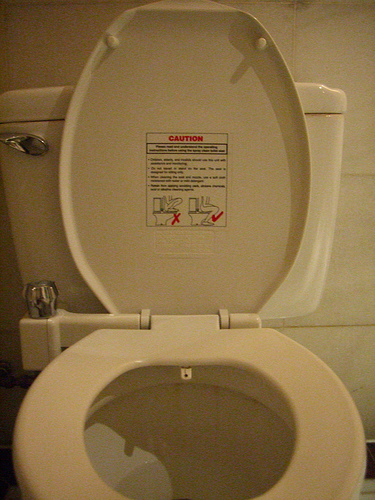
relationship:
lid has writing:
[58, 0, 309, 314] [168, 135, 202, 141]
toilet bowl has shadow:
[5, 329, 369, 498] [78, 359, 302, 498]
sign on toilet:
[146, 132, 228, 228] [2, 3, 368, 498]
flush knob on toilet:
[0, 123, 53, 159] [2, 3, 368, 498]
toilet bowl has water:
[5, 329, 369, 498] [105, 443, 261, 499]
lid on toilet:
[54, 11, 315, 320] [5, 14, 347, 488]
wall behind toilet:
[9, 16, 352, 374] [2, 3, 368, 498]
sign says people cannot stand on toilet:
[141, 128, 233, 232] [150, 194, 177, 225]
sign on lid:
[146, 132, 228, 228] [58, 0, 309, 314]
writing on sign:
[166, 130, 204, 141] [146, 132, 228, 228]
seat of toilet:
[11, 319, 362, 490] [5, 14, 347, 488]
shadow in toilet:
[85, 383, 293, 498] [2, 3, 368, 498]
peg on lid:
[100, 31, 121, 46] [58, 0, 309, 314]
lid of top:
[7, 79, 347, 126] [9, 83, 345, 328]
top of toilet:
[9, 83, 345, 328] [5, 14, 347, 488]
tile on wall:
[293, 8, 357, 172] [12, 6, 362, 330]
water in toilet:
[130, 468, 241, 491] [2, 3, 368, 498]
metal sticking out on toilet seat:
[177, 368, 189, 380] [9, 316, 359, 487]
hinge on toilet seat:
[137, 305, 152, 328] [9, 316, 359, 487]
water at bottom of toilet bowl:
[123, 453, 241, 490] [88, 365, 278, 497]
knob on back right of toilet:
[19, 278, 68, 314] [2, 3, 368, 498]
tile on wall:
[294, 8, 374, 174] [19, 19, 359, 411]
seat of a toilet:
[11, 319, 362, 490] [2, 3, 368, 498]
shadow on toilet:
[85, 383, 293, 498] [35, 382, 242, 459]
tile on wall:
[294, 8, 374, 174] [340, 265, 365, 319]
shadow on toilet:
[194, 403, 246, 450] [65, 378, 315, 486]